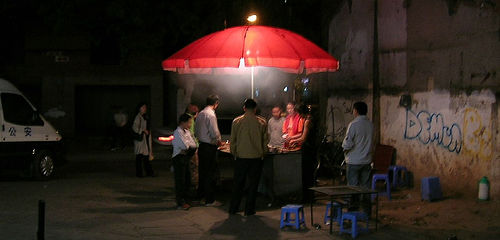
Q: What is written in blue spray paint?
A: Demon.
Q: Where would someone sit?
A: Small blue stools.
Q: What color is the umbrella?
A: Red.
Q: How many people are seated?
A: None.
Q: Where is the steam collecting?
A: Under the umbrella.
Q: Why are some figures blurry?
A: Slow shutter speed.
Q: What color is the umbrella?
A: Red.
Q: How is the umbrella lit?
A: With a light.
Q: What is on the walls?
A: Graffiti.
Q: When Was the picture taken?
A: At night.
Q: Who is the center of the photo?
A: The street vendor.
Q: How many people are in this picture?
A: Eight.